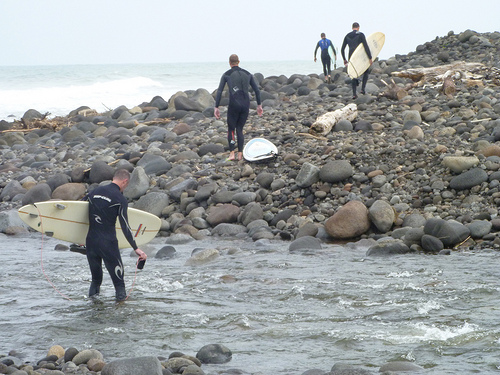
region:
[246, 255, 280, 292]
part of a water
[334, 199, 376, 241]
part of a stone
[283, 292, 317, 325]
part of a splash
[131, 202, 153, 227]
edge of a board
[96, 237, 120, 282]
part of a costume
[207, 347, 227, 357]
edge of a rock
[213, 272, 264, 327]
part of a splash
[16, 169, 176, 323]
a man holding his surf board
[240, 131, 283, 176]
a surf board on the ground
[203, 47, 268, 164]
a man walking on the rocks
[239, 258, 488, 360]
water splashing in the rocks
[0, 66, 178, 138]
some foamy waves hiting the coast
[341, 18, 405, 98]
a man holding his surfboard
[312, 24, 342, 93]
a man holding his surfboard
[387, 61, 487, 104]
washed up trees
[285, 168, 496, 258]
large rocks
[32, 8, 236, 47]
a clear sky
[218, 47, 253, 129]
this is a man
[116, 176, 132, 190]
the man is light skinned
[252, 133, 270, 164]
this is a surf board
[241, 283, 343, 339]
this is a water body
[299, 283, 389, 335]
water is flowing calmly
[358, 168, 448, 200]
these is are small rocks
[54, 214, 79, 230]
the surf board is white in color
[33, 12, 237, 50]
this is the sky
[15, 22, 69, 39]
the sky is blue in color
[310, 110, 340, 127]
this is a log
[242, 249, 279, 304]
part of a water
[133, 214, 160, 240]
part of a board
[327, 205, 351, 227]
edge of a rock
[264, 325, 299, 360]
part of a water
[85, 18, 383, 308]
four people on seashore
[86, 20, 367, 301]
four surfers in a seashore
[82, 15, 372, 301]
two surfers holding their white surfboards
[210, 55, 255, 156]
surfer in black wetsuit with his surfboard ona side in the ground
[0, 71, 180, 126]
white waves in the sea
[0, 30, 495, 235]
bunch of rocks in a seashore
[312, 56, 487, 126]
two brown small stumps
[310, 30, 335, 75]
man in blue and black wetsuit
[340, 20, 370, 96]
man in black suit holding his surftable in his right arm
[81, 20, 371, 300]
three surfers in black wetsuits and one in blue wetsuit